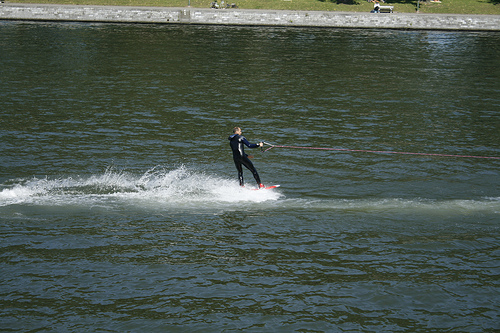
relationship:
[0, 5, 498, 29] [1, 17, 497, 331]
wall built along edge of water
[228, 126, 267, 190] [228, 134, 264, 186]
man in a wetsuit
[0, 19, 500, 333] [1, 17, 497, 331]
ripple in water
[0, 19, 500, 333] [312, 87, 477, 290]
ripple in water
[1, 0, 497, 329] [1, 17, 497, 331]
ripple in water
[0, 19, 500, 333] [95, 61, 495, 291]
ripple in water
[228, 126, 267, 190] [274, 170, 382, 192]
man in water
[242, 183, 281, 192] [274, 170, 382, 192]
board in water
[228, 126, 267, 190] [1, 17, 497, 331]
man in water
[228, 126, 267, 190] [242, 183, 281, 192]
man standing on board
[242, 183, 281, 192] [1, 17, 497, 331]
board in water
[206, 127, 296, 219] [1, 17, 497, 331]
ski coming out of water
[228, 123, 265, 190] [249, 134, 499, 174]
man holding line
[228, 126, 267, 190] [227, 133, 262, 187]
man wearing wet suit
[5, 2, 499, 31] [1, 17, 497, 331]
shoreline along side water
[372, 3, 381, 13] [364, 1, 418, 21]
person sitting on bench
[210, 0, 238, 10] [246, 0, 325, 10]
people on grass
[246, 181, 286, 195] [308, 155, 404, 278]
board in water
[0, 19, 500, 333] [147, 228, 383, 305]
ripple in water